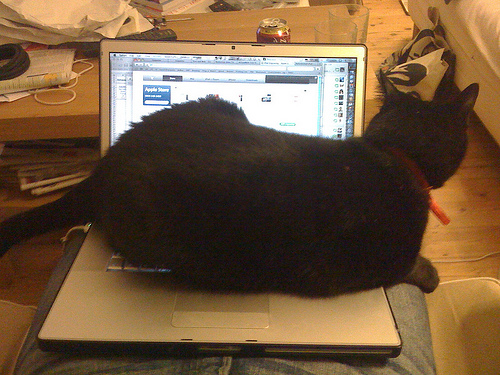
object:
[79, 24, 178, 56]
remote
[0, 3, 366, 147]
table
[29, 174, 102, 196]
papers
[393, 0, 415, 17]
remote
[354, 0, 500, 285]
floor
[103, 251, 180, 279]
laptop keyboard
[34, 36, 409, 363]
laptop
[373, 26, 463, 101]
pillow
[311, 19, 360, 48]
glass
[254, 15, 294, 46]
cola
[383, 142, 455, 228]
collar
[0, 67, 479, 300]
cat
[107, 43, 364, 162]
laptop screen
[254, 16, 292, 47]
soda can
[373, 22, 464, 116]
tote bag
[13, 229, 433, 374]
jeans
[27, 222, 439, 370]
lap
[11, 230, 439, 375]
man